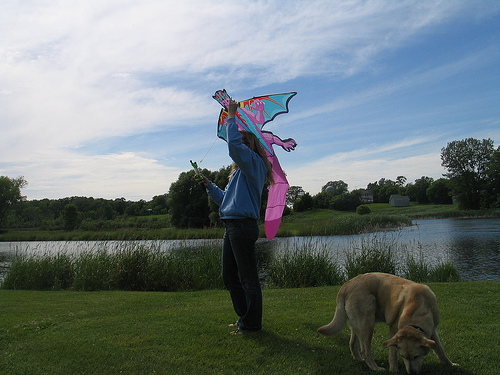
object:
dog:
[318, 272, 461, 374]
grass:
[0, 287, 498, 374]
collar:
[408, 325, 424, 332]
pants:
[221, 219, 263, 331]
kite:
[212, 88, 297, 239]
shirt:
[206, 118, 269, 220]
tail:
[318, 292, 346, 337]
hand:
[228, 97, 239, 115]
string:
[199, 137, 219, 165]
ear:
[420, 338, 439, 351]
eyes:
[414, 356, 419, 360]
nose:
[405, 367, 416, 373]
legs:
[346, 310, 376, 363]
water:
[1, 216, 499, 285]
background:
[1, 143, 496, 303]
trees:
[440, 138, 500, 209]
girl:
[192, 97, 273, 337]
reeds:
[2, 220, 460, 290]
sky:
[0, 0, 499, 204]